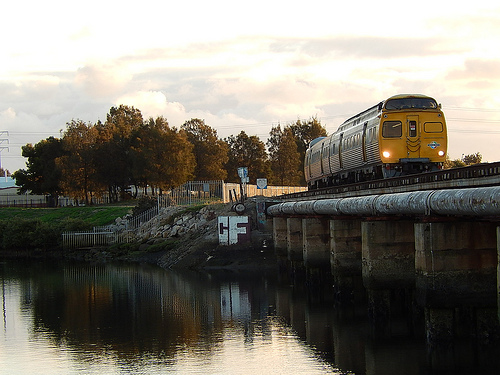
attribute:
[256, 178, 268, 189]
sign — street sign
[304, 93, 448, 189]
train — yellow, black, here, uncommon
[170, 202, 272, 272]
wall — spraypainted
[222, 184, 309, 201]
spraypaint — red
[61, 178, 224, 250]
fence — metal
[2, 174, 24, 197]
building — tan, red, white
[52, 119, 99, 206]
tree — brown, green, dark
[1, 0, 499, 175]
sky — blue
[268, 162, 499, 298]
bridge — here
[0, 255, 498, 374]
water — calm, reflecting, black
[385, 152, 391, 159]
light — on, shining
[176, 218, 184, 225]
rock — on shore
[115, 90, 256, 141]
cloud — puffy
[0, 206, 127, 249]
riverbank — grassy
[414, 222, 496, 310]
column — cement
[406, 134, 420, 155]
chain — three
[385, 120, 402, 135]
window — squarish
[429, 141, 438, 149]
logo — blue